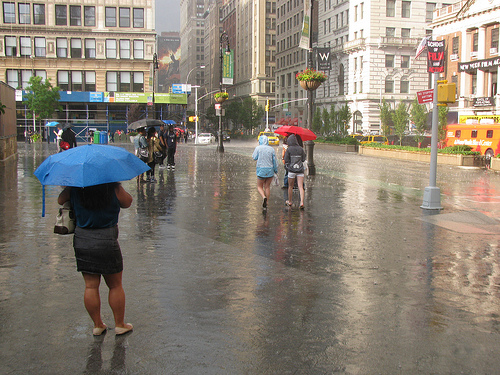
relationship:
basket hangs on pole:
[297, 80, 322, 89] [303, 1, 317, 174]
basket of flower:
[297, 80, 322, 89] [294, 67, 327, 82]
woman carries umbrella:
[57, 183, 133, 335] [36, 142, 151, 219]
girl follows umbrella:
[280, 133, 307, 210] [271, 123, 317, 143]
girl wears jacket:
[251, 130, 278, 211] [249, 134, 277, 178]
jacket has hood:
[249, 134, 277, 178] [256, 132, 268, 144]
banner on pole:
[297, 0, 314, 52] [303, 1, 317, 174]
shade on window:
[85, 72, 94, 85] [85, 69, 94, 90]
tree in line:
[379, 95, 391, 143] [375, 97, 429, 146]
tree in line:
[393, 97, 408, 143] [375, 97, 429, 146]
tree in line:
[409, 95, 426, 146] [375, 97, 429, 146]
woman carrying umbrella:
[57, 183, 133, 335] [36, 142, 151, 219]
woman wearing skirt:
[57, 183, 133, 335] [71, 229, 125, 275]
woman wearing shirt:
[57, 183, 133, 335] [68, 182, 119, 229]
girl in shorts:
[280, 133, 307, 210] [287, 169, 307, 179]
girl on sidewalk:
[280, 133, 307, 210] [3, 138, 499, 366]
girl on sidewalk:
[251, 130, 278, 211] [3, 138, 499, 366]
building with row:
[1, 1, 159, 132] [5, 65, 145, 101]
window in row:
[85, 69, 94, 90] [5, 65, 145, 101]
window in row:
[130, 69, 143, 93] [5, 65, 145, 101]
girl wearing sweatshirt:
[280, 133, 307, 210] [282, 132, 309, 174]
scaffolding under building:
[16, 100, 112, 145] [1, 1, 159, 132]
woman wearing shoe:
[57, 183, 133, 335] [114, 321, 131, 336]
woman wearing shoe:
[57, 183, 133, 335] [92, 325, 106, 337]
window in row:
[5, 67, 20, 90] [5, 65, 145, 101]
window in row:
[2, 35, 17, 55] [3, 33, 148, 61]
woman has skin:
[57, 183, 133, 335] [79, 271, 132, 328]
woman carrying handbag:
[57, 183, 133, 335] [52, 203, 73, 234]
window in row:
[131, 39, 145, 61] [3, 33, 148, 61]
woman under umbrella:
[57, 183, 133, 335] [36, 142, 151, 219]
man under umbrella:
[133, 128, 146, 186] [126, 116, 166, 132]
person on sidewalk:
[163, 125, 178, 171] [3, 138, 499, 366]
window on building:
[381, 78, 393, 93] [314, 3, 432, 134]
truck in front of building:
[438, 121, 498, 156] [429, 1, 497, 123]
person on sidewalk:
[52, 123, 63, 152] [3, 138, 499, 366]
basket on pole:
[213, 93, 227, 102] [213, 30, 229, 151]